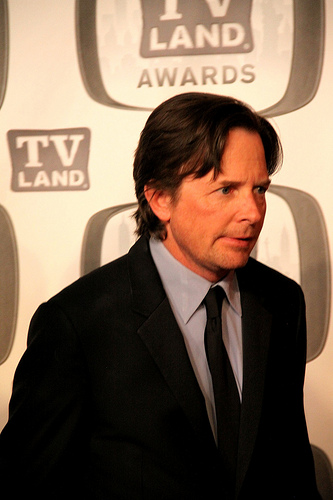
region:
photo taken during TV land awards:
[3, 1, 323, 493]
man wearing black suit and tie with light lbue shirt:
[1, 88, 322, 492]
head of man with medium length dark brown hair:
[124, 102, 290, 270]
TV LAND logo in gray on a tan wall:
[0, 127, 97, 203]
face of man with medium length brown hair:
[170, 128, 273, 273]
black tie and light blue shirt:
[146, 238, 245, 473]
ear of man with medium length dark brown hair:
[140, 170, 170, 233]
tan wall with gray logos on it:
[0, 0, 332, 450]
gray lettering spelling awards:
[134, 62, 256, 92]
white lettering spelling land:
[7, 167, 90, 193]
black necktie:
[200, 279, 242, 467]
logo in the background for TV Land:
[8, 128, 91, 192]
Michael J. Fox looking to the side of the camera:
[7, 87, 316, 497]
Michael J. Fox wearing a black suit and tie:
[13, 88, 315, 499]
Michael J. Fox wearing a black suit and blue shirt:
[17, 84, 317, 498]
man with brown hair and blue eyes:
[130, 91, 276, 268]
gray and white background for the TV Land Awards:
[4, 0, 133, 192]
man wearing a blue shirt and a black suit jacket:
[31, 91, 314, 498]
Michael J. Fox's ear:
[146, 179, 171, 221]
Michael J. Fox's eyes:
[214, 183, 266, 196]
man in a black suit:
[2, 90, 323, 499]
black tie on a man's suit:
[203, 285, 240, 479]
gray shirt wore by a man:
[148, 234, 241, 448]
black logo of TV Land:
[6, 126, 93, 191]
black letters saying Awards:
[137, 64, 254, 85]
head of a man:
[133, 91, 279, 267]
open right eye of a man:
[213, 186, 233, 195]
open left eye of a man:
[252, 187, 267, 193]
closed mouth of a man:
[219, 234, 255, 243]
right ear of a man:
[143, 178, 170, 219]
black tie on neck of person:
[196, 283, 256, 447]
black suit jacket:
[0, 230, 323, 498]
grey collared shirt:
[144, 232, 248, 457]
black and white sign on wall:
[2, 121, 109, 199]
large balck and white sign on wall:
[70, 0, 329, 122]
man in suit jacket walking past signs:
[0, 79, 327, 493]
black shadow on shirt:
[181, 336, 221, 453]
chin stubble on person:
[203, 246, 241, 271]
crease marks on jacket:
[1, 307, 43, 437]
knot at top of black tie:
[203, 285, 229, 324]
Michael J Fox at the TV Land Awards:
[114, 0, 289, 300]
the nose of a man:
[234, 197, 262, 225]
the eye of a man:
[207, 181, 237, 197]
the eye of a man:
[251, 182, 270, 196]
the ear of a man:
[142, 177, 179, 224]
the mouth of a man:
[216, 230, 256, 245]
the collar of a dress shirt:
[147, 236, 208, 323]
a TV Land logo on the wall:
[5, 127, 97, 196]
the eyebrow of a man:
[212, 177, 243, 185]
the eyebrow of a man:
[252, 176, 273, 187]